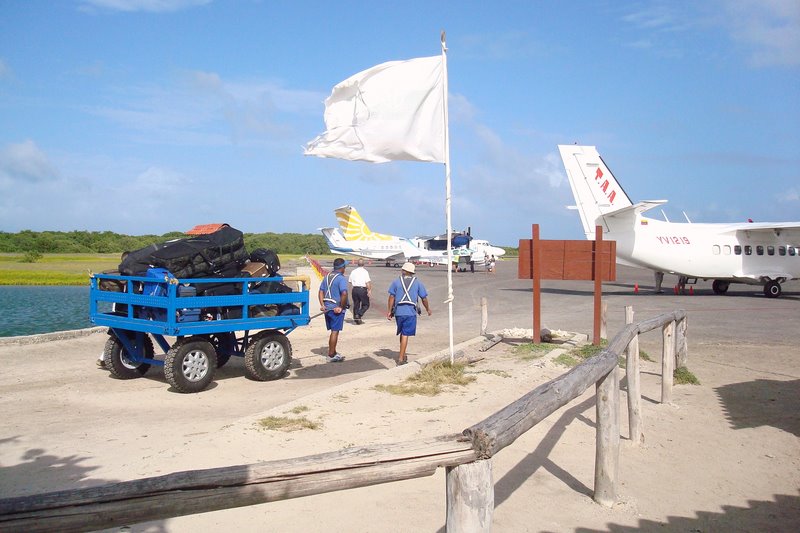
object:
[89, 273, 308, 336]
cart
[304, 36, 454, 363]
flag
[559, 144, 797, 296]
plane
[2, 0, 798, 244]
sky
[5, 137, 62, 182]
cloud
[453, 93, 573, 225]
cloud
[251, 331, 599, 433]
sand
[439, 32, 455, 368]
pole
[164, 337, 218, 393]
back wheel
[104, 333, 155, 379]
back wheel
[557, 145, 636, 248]
tail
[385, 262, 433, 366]
man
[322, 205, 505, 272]
plane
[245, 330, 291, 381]
wheel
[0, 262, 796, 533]
floor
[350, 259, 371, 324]
men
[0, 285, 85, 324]
pond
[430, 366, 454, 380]
patch of grass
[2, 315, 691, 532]
fence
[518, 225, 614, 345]
sign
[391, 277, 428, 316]
shirt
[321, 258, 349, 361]
man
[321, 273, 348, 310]
shirt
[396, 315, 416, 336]
shorts